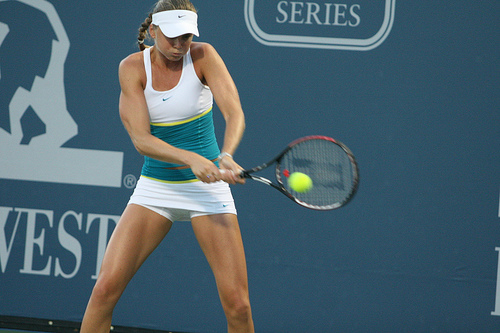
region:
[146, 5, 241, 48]
Woman wearing white visor.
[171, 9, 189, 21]
Nike swoosh on visor.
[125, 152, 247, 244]
Woman wearing white skirt.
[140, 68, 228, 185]
Woman wearing Nike tank top.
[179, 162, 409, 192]
Woman holding tennis racket.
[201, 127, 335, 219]
Woman hitting a tennis ball.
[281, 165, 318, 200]
Tennis ball is yellowish green in color.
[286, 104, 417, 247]
Blue wall behind player.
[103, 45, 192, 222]
Woman has muscular arms.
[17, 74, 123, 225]
White writing on blue wall.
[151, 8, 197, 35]
white visor with a black swoosh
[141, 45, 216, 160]
white and green tank top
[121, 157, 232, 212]
white and green skirt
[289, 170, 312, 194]
green tennis ball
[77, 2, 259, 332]
woman playing tennis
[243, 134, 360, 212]
tennis ball about to hit racquet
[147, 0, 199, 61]
white visor on woman's head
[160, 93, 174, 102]
green swoosh on tank top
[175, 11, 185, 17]
black swoosh on visor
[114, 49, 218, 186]
woman's muscular arm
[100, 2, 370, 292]
blond woman playing tennis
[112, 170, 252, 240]
woman wearing white shorts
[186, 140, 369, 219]
woman holding tennis racket with two hands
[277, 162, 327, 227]
tennis ball i sin mid air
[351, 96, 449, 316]
blue wall is the background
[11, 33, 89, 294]
white lettering on the blue wall for advertiser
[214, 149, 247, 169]
woman wearing bracelet or watch on left wrist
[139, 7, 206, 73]
woman wearing white visor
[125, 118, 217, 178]
middle of woman's shirt is turquoise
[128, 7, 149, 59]
woman's hair is in a braid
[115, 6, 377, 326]
She is playing tennis.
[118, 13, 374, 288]
She is swinging the racket.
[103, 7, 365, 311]
She is hitting the ball.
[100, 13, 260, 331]
She is wearing a white and blue outfit.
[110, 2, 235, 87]
She is wearing a white visor.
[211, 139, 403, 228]
The racket is hitting the ball.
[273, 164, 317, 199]
The ball is yellow.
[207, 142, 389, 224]
The racket is black and red.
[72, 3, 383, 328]
She is playing hard.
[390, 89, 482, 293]
The background is blue.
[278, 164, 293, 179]
red spot on tennis racket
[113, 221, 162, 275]
tennis player muscular legs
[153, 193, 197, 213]
edge of white tennis skirt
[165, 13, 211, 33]
swoosh on white sun visor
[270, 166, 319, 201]
yellow tennis being hit by player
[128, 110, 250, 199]
blue mid section of dress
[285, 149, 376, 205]
clear strings in racket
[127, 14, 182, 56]
woman's blond pony tail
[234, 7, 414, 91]
white logo on wall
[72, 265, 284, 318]
knees on tennis player